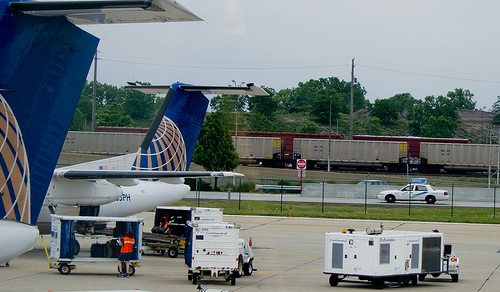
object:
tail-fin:
[0, 0, 206, 228]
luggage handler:
[116, 230, 134, 277]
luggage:
[88, 239, 120, 258]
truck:
[185, 222, 256, 285]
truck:
[73, 205, 224, 258]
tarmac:
[0, 216, 499, 291]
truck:
[323, 223, 460, 289]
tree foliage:
[79, 74, 468, 135]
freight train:
[60, 126, 497, 177]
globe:
[129, 115, 188, 172]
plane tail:
[123, 80, 272, 171]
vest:
[120, 237, 135, 253]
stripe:
[123, 240, 134, 244]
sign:
[411, 178, 427, 185]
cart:
[49, 214, 145, 279]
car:
[377, 178, 451, 204]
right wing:
[53, 169, 243, 187]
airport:
[4, 2, 498, 291]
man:
[115, 231, 137, 278]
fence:
[189, 179, 500, 220]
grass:
[181, 197, 498, 225]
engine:
[47, 178, 122, 206]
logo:
[130, 116, 187, 172]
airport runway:
[5, 212, 498, 288]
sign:
[297, 159, 307, 170]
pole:
[300, 169, 303, 195]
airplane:
[41, 81, 270, 258]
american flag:
[99, 166, 109, 170]